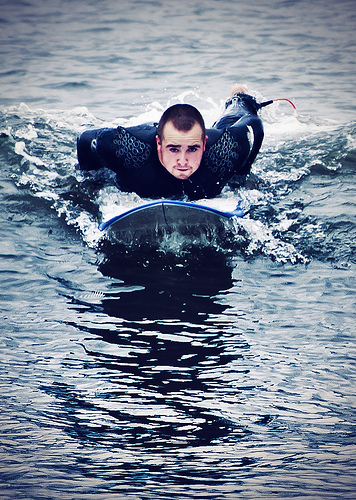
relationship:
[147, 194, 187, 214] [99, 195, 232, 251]
tip of surfboard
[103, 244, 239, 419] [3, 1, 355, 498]
shadow on water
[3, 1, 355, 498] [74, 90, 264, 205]
water by man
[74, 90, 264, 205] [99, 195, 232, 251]
man on surfboard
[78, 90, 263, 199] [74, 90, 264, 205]
wetsuit on man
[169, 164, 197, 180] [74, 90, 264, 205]
beard on man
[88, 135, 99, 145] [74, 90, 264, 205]
logo on man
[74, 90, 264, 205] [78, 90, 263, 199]
man in wetsuit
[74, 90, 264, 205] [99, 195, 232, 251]
man laying on surfboard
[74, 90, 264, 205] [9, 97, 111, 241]
man making a wave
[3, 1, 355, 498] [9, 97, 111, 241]
water with a wave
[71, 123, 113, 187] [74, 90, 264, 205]
arm on man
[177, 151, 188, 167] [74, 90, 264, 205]
nose on man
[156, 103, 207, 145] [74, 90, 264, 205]
hair on man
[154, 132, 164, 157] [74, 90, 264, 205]
ear on man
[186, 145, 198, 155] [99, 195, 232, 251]
eye on surfboard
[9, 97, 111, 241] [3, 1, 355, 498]
wave in water